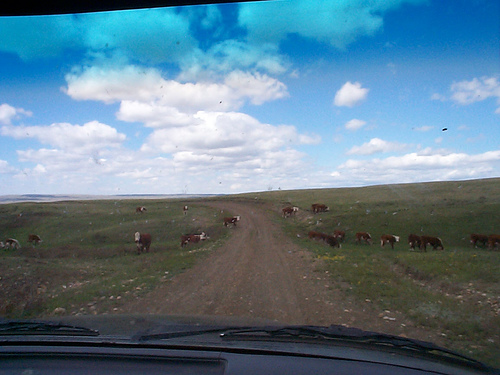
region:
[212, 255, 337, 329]
the road is rocky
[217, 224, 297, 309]
the road is brown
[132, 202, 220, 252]
the animals are cows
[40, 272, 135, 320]
rocks in the pasture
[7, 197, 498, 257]
A herd of cattle in a field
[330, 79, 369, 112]
A round white cloud in the sky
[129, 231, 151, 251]
A brown cow with a white face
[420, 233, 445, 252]
A brown cow grazing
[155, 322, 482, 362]
A black windshield wiper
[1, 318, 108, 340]
A windshield wiper on a car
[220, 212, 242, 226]
A cow on a dirt road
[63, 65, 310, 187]
A large white cloud in the sky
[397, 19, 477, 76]
Blue sky near the clouds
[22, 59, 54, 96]
white clouds in blue sky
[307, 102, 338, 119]
white clouds in blue sky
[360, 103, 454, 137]
white clouds in blue sky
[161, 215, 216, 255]
brown cow in field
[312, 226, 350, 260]
brown cow in field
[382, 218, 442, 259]
brown cow in field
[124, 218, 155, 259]
brown and white cow in field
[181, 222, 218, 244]
brown and white cow in field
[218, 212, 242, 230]
brown and white cow in field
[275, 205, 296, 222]
brown and white cow in field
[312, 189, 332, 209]
brown and white cow in field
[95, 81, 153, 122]
white clouds in blue sky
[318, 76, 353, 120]
white clouds in blue sky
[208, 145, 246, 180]
white clouds in blue sky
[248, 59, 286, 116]
white clouds in blue sky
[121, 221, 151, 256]
brown cow in green field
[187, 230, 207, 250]
brown cow in green field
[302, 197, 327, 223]
brown cow in green field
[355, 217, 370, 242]
brown cow in green field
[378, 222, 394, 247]
brown cow in green field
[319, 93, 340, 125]
white clouds in blue sky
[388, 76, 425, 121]
white clouds in blue sky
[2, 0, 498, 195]
a blue cloudy sky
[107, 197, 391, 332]
a dirt path road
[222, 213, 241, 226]
a brown and white cow standing in road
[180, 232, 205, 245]
a brown and white cow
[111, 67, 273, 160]
the sky is very cloudy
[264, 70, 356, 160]
the sky is light blue and white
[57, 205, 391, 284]
these are a herd of cattle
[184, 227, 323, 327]
the road is brown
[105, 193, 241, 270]
the cows are grazing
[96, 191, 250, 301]
the cows are white and brown